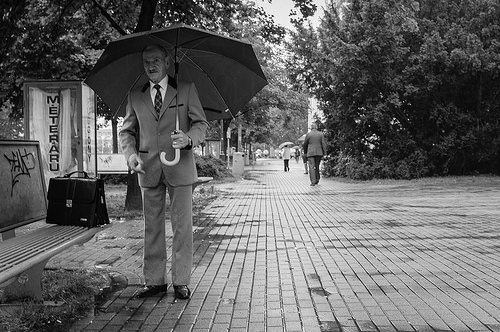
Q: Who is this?
A: A man.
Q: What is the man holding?
A: An umbrella.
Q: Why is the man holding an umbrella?
A: It's raining.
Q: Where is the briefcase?
A: On the bench.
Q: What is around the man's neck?
A: A tie.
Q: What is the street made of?
A: Brick.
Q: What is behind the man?
A: Trees and other people walking.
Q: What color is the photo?
A: Black and white.